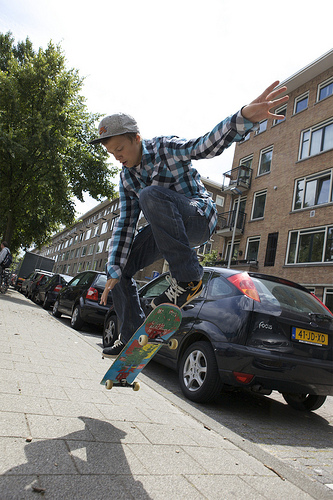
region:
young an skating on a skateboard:
[44, 78, 310, 404]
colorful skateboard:
[100, 293, 220, 405]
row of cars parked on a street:
[29, 232, 303, 406]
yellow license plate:
[284, 308, 323, 370]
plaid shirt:
[92, 81, 270, 269]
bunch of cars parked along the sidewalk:
[27, 222, 325, 415]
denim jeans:
[69, 189, 230, 332]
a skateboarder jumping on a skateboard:
[72, 94, 291, 399]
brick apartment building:
[181, 143, 309, 319]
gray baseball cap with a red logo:
[68, 87, 155, 157]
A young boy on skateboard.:
[82, 104, 232, 495]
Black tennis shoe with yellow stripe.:
[155, 268, 212, 307]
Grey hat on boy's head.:
[89, 101, 147, 167]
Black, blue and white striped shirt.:
[110, 136, 216, 233]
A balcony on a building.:
[217, 157, 260, 203]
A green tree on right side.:
[1, 65, 89, 251]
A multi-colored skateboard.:
[103, 295, 180, 398]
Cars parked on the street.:
[17, 247, 114, 332]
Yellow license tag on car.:
[288, 314, 332, 353]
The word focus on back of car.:
[251, 310, 280, 336]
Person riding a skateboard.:
[79, 77, 293, 389]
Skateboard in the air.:
[92, 299, 178, 398]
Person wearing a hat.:
[90, 76, 284, 356]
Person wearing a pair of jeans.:
[90, 76, 283, 355]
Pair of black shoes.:
[95, 277, 204, 357]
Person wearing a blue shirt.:
[85, 74, 288, 355]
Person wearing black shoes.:
[85, 75, 289, 359]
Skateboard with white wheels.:
[98, 300, 187, 393]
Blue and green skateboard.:
[95, 299, 186, 393]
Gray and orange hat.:
[86, 108, 147, 146]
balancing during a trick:
[88, 74, 297, 395]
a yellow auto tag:
[279, 322, 331, 351]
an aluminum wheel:
[172, 341, 216, 402]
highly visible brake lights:
[225, 269, 330, 316]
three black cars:
[41, 262, 328, 413]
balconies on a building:
[213, 153, 261, 240]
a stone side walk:
[1, 287, 294, 492]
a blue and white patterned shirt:
[91, 102, 256, 277]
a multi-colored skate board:
[88, 291, 193, 396]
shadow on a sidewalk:
[0, 406, 158, 499]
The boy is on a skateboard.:
[68, 77, 287, 399]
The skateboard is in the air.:
[91, 298, 194, 415]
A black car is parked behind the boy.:
[96, 256, 330, 431]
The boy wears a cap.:
[80, 108, 145, 149]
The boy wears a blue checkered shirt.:
[102, 134, 239, 283]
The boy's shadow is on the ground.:
[1, 402, 152, 497]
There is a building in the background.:
[228, 77, 332, 293]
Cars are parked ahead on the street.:
[20, 257, 127, 335]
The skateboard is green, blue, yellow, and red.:
[99, 301, 182, 396]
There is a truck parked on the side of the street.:
[10, 245, 57, 300]